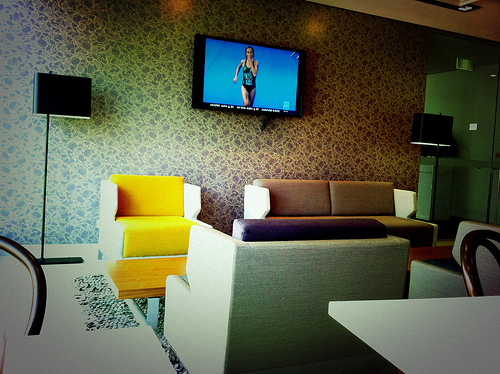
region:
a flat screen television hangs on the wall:
[187, 31, 306, 118]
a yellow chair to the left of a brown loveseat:
[99, 174, 214, 259]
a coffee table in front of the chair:
[103, 252, 183, 326]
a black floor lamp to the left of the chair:
[28, 68, 93, 263]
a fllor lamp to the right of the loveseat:
[409, 107, 461, 219]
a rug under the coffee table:
[72, 273, 172, 329]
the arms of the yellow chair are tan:
[98, 178, 124, 260]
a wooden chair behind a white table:
[325, 297, 499, 372]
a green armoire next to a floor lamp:
[416, 68, 498, 221]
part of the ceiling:
[317, 0, 499, 35]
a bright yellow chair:
[98, 163, 205, 255]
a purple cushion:
[168, 209, 396, 256]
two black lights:
[28, 60, 455, 191]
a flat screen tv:
[188, 30, 313, 120]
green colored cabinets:
[425, 60, 498, 215]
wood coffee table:
[105, 251, 195, 297]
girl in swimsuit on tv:
[192, 30, 313, 120]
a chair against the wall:
[85, 165, 225, 260]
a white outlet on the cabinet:
[465, 117, 480, 132]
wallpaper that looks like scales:
[16, 30, 191, 227]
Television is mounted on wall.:
[179, 24, 324, 124]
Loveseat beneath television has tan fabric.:
[240, 172, 438, 260]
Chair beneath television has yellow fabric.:
[99, 164, 212, 279]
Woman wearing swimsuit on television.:
[224, 38, 266, 108]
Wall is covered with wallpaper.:
[0, 0, 499, 246]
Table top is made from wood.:
[99, 240, 205, 304]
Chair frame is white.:
[89, 170, 216, 274]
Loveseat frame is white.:
[238, 169, 425, 258]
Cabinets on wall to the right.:
[413, 66, 499, 247]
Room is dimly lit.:
[3, 1, 498, 370]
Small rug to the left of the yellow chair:
[73, 278, 118, 326]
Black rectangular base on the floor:
[36, 249, 88, 267]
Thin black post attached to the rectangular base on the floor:
[38, 121, 58, 259]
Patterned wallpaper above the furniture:
[116, 115, 228, 167]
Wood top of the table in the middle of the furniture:
[96, 256, 161, 294]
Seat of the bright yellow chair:
[129, 216, 184, 231]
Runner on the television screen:
[233, 43, 262, 105]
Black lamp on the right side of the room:
[404, 105, 456, 152]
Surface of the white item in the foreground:
[367, 296, 484, 365]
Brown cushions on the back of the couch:
[273, 176, 390, 215]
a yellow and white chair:
[91, 169, 208, 258]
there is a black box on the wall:
[28, 70, 93, 265]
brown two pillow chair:
[227, 174, 442, 243]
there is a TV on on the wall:
[192, 32, 315, 119]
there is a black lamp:
[412, 107, 456, 224]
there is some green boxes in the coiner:
[413, 61, 496, 229]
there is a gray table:
[324, 286, 499, 371]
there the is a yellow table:
[97, 253, 189, 320]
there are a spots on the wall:
[0, 3, 499, 247]